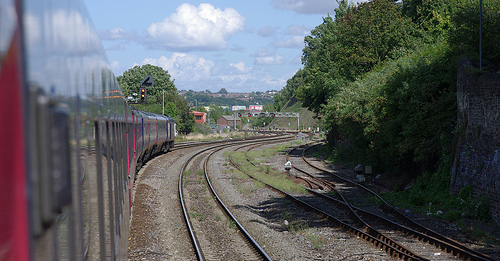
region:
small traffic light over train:
[132, 72, 159, 103]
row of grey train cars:
[15, 0, 178, 253]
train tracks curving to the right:
[173, 122, 393, 259]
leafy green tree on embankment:
[306, 5, 410, 121]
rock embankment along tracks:
[445, 54, 499, 217]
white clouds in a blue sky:
[98, 0, 333, 87]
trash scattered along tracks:
[345, 152, 400, 193]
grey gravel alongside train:
[127, 149, 189, 259]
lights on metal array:
[222, 102, 304, 137]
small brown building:
[215, 110, 243, 128]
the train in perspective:
[1, 6, 183, 259]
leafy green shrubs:
[296, 11, 459, 183]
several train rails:
[178, 133, 381, 258]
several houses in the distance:
[193, 99, 263, 136]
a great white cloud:
[143, 5, 298, 91]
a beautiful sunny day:
[141, 8, 292, 93]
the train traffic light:
[136, 77, 163, 109]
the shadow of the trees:
[235, 177, 452, 249]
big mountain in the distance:
[172, 76, 282, 102]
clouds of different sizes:
[151, 7, 305, 91]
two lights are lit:
[125, 56, 166, 113]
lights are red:
[134, 72, 155, 101]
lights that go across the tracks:
[235, 106, 314, 123]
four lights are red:
[231, 98, 289, 123]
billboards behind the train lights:
[212, 95, 273, 109]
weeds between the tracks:
[184, 145, 235, 259]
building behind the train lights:
[220, 107, 246, 123]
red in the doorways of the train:
[95, 84, 174, 168]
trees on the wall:
[304, 15, 498, 185]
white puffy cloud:
[155, 13, 237, 61]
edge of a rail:
[223, 207, 248, 238]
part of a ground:
[275, 219, 307, 248]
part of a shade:
[253, 185, 290, 236]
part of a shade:
[239, 192, 262, 216]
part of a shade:
[276, 190, 344, 250]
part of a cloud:
[176, 0, 235, 83]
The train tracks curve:
[168, 148, 221, 186]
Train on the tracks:
[88, 58, 130, 235]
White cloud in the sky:
[148, 5, 243, 42]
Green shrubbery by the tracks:
[338, 46, 421, 129]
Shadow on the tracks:
[271, 200, 381, 225]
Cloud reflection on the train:
[46, 18, 92, 54]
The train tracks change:
[298, 173, 425, 230]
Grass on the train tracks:
[237, 153, 277, 191]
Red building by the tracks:
[193, 110, 208, 124]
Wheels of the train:
[139, 142, 164, 164]